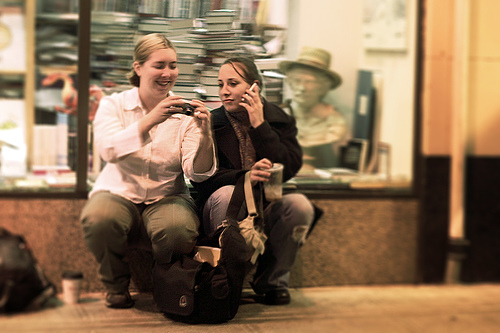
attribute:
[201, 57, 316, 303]
woman — squatting, looking, talking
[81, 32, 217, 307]
woman — smiling, squatting, blonde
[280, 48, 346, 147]
bust — a head, male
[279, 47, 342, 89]
hat — brown, large, beige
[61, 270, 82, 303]
coffe cup — black, styrofoam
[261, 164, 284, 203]
cup — plastic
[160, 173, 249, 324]
bag — black, hobo style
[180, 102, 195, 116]
camera — silver, digital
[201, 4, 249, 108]
books — stacked, on display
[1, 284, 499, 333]
sidewalk — concrete, for a city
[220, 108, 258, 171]
scarf — knit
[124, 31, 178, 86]
hair — blonde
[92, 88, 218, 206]
shirt — white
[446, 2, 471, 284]
pole — white, long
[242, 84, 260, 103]
cellphone — gray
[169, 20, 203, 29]
book — large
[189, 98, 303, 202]
jacket — black